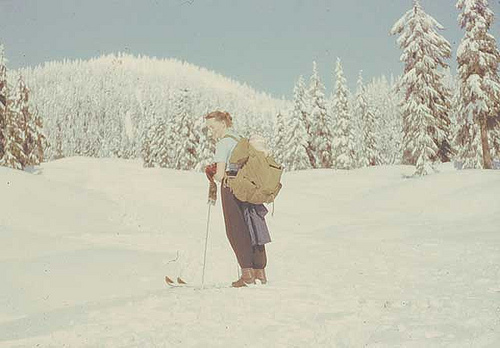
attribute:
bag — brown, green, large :
[221, 135, 284, 207]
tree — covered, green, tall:
[392, 5, 461, 168]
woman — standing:
[206, 110, 269, 287]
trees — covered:
[0, 5, 498, 171]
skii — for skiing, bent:
[164, 275, 287, 287]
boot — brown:
[232, 269, 255, 286]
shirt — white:
[214, 128, 242, 176]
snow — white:
[8, 159, 499, 337]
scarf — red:
[204, 164, 219, 209]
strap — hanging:
[271, 195, 276, 214]